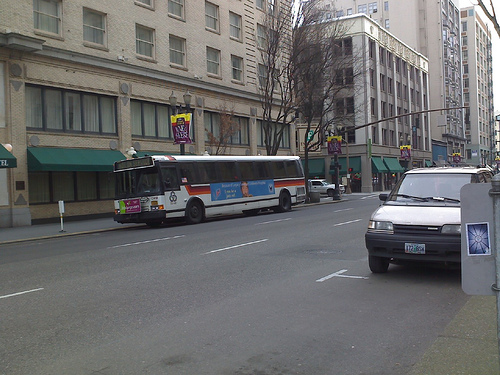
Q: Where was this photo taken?
A: On a city street.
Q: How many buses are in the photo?
A: One.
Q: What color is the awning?
A: Green.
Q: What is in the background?
A: Buildings.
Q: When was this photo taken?
A: In the daytime.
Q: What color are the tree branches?
A: Brown.